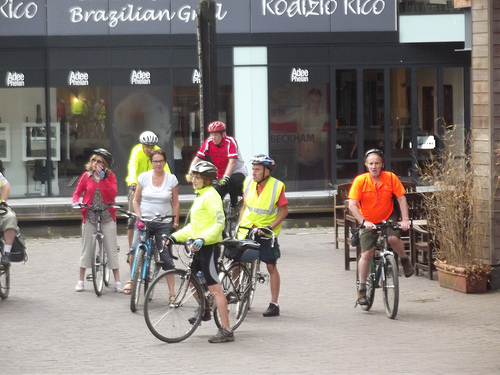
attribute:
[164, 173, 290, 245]
tops — green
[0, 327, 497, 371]
surface — paved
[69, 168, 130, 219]
sweater — red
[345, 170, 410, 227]
shirt — orange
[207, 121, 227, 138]
helmet — red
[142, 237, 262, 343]
bike — angled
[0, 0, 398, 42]
awning — grey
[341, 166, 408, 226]
top — orange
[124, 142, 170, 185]
jacket — bright, yellow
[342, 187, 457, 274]
table — dark, wooden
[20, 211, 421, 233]
water — gray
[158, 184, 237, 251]
yellow shirt — bright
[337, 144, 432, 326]
shirt — orange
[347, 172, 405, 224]
shirt — orange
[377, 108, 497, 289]
plant — dead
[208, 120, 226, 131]
helmet — red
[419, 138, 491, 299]
vegetation — brown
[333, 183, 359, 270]
chairs — wooden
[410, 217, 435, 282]
chairs — wooden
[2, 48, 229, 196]
window — large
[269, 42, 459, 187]
window — large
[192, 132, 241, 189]
shirt — red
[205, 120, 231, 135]
helmet — red